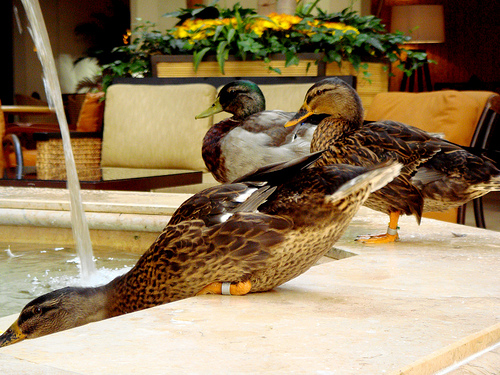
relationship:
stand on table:
[0, 129, 27, 178] [0, 101, 70, 114]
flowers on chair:
[170, 10, 362, 45] [103, 75, 210, 192]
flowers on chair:
[170, 10, 362, 45] [214, 80, 315, 123]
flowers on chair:
[170, 10, 362, 45] [363, 90, 498, 228]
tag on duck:
[386, 226, 406, 237] [294, 74, 495, 254]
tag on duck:
[220, 273, 237, 290] [191, 72, 311, 164]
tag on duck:
[386, 226, 406, 237] [0, 148, 404, 344]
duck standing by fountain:
[189, 73, 316, 178] [1, 6, 166, 322]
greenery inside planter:
[74, 1, 443, 82] [149, 48, 419, 99]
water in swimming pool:
[1, 2, 153, 319] [1, 180, 498, 373]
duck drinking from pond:
[8, 155, 358, 342] [0, 200, 355, 345]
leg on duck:
[193, 268, 269, 305] [294, 45, 492, 269]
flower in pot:
[337, 17, 361, 35] [143, 40, 395, 107]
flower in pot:
[319, 17, 349, 37] [143, 40, 395, 107]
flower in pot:
[275, 20, 291, 34] [143, 40, 395, 107]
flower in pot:
[242, 17, 265, 43] [143, 40, 395, 107]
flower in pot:
[170, 20, 192, 48] [143, 40, 395, 107]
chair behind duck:
[404, 90, 499, 240] [290, 70, 482, 259]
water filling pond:
[0, 240, 146, 319] [2, 185, 487, 372]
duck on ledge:
[0, 148, 404, 344] [1, 197, 179, 229]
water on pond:
[0, 240, 146, 319] [0, 200, 355, 345]